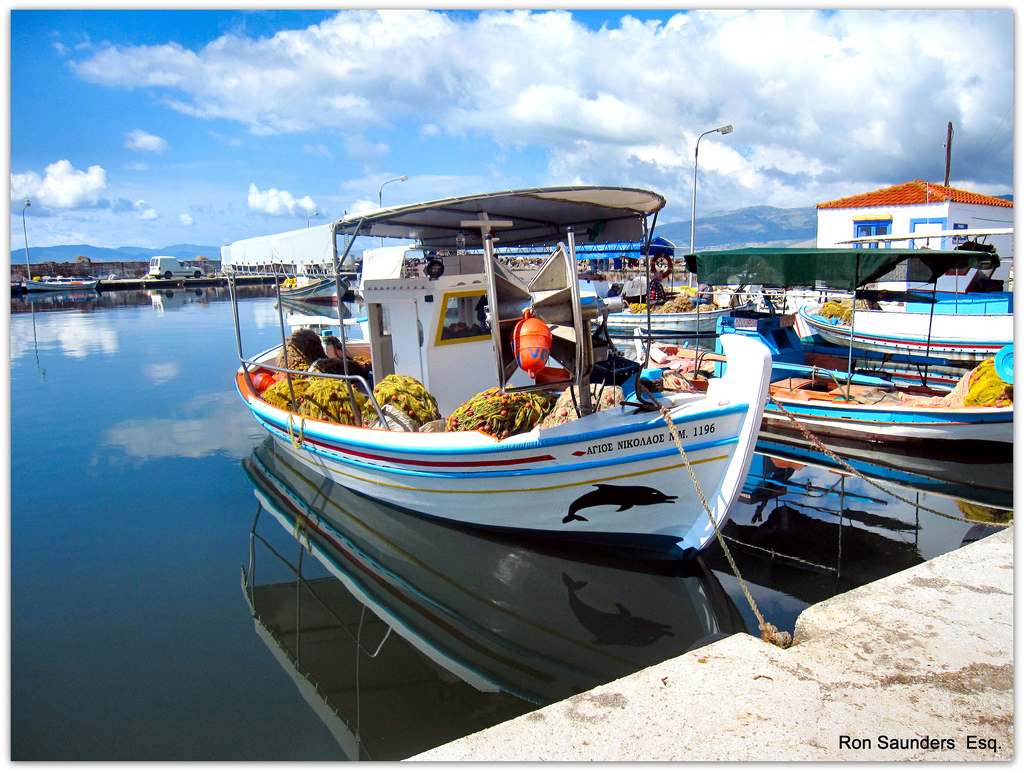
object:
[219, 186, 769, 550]
boat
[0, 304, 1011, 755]
water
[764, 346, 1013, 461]
boat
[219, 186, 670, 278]
canopy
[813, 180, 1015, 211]
roof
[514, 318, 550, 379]
buoy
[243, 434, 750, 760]
reflection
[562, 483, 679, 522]
picture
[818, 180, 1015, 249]
building